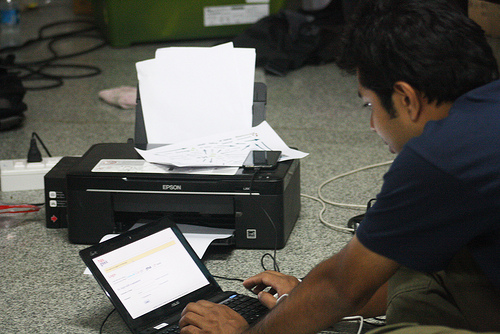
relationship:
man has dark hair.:
[171, 0, 499, 334] [336, 0, 500, 118]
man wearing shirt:
[171, 0, 499, 334] [355, 103, 497, 333]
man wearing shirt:
[171, 0, 499, 334] [355, 77, 500, 289]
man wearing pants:
[171, 0, 499, 334] [381, 253, 496, 332]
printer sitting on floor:
[37, 126, 302, 271] [27, 206, 81, 331]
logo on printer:
[162, 184, 181, 190] [42, 77, 331, 232]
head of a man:
[333, 0, 498, 153] [171, 0, 499, 334]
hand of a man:
[178, 288, 251, 332] [199, 21, 475, 332]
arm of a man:
[182, 129, 466, 333] [171, 0, 499, 334]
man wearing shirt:
[176, 8, 500, 334] [358, 93, 495, 269]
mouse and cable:
[250, 273, 287, 293] [302, 149, 385, 239]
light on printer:
[47, 213, 59, 222] [33, 42, 300, 249]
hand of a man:
[246, 269, 301, 303] [137, 5, 498, 332]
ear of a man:
[394, 79, 423, 117] [159, 11, 488, 331]